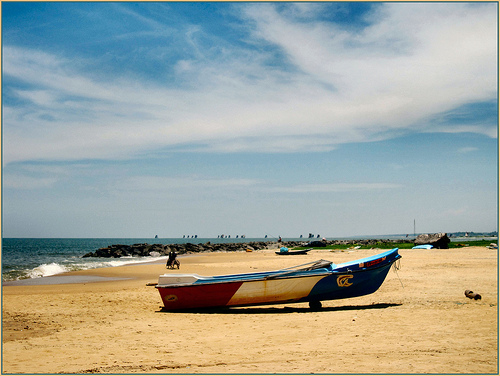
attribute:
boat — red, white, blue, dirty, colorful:
[143, 245, 405, 315]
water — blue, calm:
[4, 237, 499, 285]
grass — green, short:
[291, 238, 498, 251]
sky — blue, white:
[4, 4, 498, 238]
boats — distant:
[151, 232, 324, 240]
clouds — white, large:
[3, 4, 499, 240]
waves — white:
[5, 250, 184, 283]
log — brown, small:
[464, 286, 481, 305]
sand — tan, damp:
[4, 246, 496, 375]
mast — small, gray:
[411, 218, 418, 243]